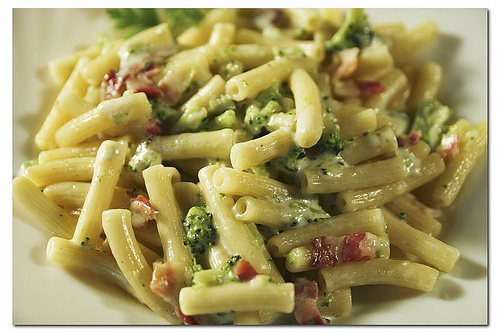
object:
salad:
[33, 13, 463, 313]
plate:
[39, 256, 458, 332]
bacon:
[116, 66, 169, 89]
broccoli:
[166, 194, 219, 244]